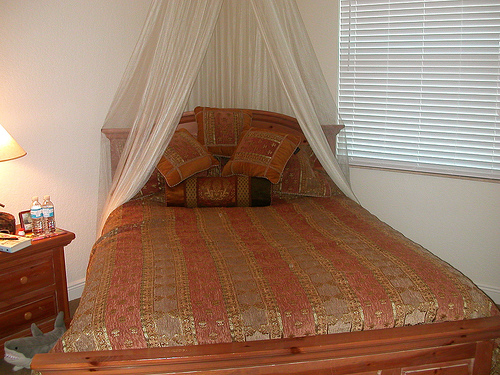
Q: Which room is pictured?
A: It is a bedroom.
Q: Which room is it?
A: It is a bedroom.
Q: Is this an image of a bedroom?
A: Yes, it is showing a bedroom.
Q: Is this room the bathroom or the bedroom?
A: It is the bedroom.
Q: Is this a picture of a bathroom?
A: No, the picture is showing a bedroom.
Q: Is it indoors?
A: Yes, it is indoors.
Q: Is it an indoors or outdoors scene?
A: It is indoors.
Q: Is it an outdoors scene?
A: No, it is indoors.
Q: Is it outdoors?
A: No, it is indoors.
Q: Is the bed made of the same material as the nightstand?
A: Yes, both the bed and the nightstand are made of wood.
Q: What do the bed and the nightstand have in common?
A: The material, both the bed and the nightstand are wooden.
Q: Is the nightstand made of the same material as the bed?
A: Yes, both the nightstand and the bed are made of wood.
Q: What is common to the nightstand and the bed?
A: The material, both the nightstand and the bed are wooden.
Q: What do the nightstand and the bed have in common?
A: The material, both the nightstand and the bed are wooden.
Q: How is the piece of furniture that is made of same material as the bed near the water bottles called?
A: The piece of furniture is a nightstand.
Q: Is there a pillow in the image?
A: Yes, there are pillows.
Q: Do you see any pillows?
A: Yes, there are pillows.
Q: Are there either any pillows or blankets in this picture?
A: Yes, there are pillows.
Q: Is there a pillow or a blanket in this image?
A: Yes, there are pillows.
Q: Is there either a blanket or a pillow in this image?
A: Yes, there are pillows.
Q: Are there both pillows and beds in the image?
A: Yes, there are both pillows and a bed.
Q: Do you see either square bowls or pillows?
A: Yes, there are square pillows.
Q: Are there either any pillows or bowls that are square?
A: Yes, the pillows are square.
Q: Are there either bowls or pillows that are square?
A: Yes, the pillows are square.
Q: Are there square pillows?
A: Yes, there are square pillows.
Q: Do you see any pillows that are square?
A: Yes, there are square pillows.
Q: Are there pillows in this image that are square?
A: Yes, there are square pillows.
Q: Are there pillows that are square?
A: Yes, there are pillows that are square.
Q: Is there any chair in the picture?
A: No, there are no chairs.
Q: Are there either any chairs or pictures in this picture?
A: No, there are no chairs or pictures.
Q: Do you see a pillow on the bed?
A: Yes, there are pillows on the bed.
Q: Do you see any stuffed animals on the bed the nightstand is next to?
A: No, there are pillows on the bed.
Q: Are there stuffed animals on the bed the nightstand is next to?
A: No, there are pillows on the bed.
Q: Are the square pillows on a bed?
A: Yes, the pillows are on a bed.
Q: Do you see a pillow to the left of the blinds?
A: Yes, there are pillows to the left of the blinds.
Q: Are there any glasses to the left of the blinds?
A: No, there are pillows to the left of the blinds.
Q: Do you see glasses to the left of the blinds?
A: No, there are pillows to the left of the blinds.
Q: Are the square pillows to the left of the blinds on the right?
A: Yes, the pillows are to the left of the blinds.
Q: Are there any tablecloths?
A: No, there are no tablecloths.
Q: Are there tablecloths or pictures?
A: No, there are no tablecloths or pictures.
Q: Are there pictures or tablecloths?
A: No, there are no tablecloths or pictures.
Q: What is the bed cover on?
A: The bed cover is on the bed.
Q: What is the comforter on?
A: The bed cover is on the bed.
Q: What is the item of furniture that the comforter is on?
A: The piece of furniture is a bed.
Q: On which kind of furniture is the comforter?
A: The comforter is on the bed.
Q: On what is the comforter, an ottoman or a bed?
A: The comforter is on a bed.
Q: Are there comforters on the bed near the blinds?
A: Yes, there is a comforter on the bed.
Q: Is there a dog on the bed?
A: No, there is a comforter on the bed.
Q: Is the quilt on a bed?
A: Yes, the quilt is on a bed.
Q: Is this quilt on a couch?
A: No, the quilt is on a bed.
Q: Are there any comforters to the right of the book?
A: Yes, there is a comforter to the right of the book.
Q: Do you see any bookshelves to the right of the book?
A: No, there is a comforter to the right of the book.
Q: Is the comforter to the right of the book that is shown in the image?
A: Yes, the comforter is to the right of the book.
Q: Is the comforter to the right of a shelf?
A: No, the comforter is to the right of the book.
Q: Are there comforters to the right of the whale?
A: Yes, there is a comforter to the right of the whale.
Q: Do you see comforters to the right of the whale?
A: Yes, there is a comforter to the right of the whale.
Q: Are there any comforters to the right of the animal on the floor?
A: Yes, there is a comforter to the right of the whale.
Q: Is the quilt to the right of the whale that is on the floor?
A: Yes, the quilt is to the right of the whale.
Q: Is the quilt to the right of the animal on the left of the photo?
A: Yes, the quilt is to the right of the whale.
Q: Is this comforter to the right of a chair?
A: No, the comforter is to the right of the whale.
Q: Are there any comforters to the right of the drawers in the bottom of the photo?
A: Yes, there is a comforter to the right of the drawers.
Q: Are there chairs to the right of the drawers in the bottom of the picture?
A: No, there is a comforter to the right of the drawers.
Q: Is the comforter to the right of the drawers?
A: Yes, the comforter is to the right of the drawers.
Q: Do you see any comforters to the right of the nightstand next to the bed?
A: Yes, there is a comforter to the right of the nightstand.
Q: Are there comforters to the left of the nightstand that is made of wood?
A: No, the comforter is to the right of the nightstand.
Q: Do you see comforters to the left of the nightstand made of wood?
A: No, the comforter is to the right of the nightstand.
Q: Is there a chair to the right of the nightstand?
A: No, there is a comforter to the right of the nightstand.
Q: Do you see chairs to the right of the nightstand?
A: No, there is a comforter to the right of the nightstand.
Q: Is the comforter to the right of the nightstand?
A: Yes, the comforter is to the right of the nightstand.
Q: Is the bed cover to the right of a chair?
A: No, the bed cover is to the right of the nightstand.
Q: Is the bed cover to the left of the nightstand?
A: No, the bed cover is to the right of the nightstand.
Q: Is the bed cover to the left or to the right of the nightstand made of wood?
A: The bed cover is to the right of the nightstand.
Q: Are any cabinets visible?
A: No, there are no cabinets.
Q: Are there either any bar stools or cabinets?
A: No, there are no cabinets or bar stools.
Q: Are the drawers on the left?
A: Yes, the drawers are on the left of the image.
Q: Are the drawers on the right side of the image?
A: No, the drawers are on the left of the image.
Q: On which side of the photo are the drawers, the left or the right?
A: The drawers are on the left of the image.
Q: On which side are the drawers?
A: The drawers are on the left of the image.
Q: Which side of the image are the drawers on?
A: The drawers are on the left of the image.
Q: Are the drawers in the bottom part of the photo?
A: Yes, the drawers are in the bottom of the image.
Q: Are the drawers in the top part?
A: No, the drawers are in the bottom of the image.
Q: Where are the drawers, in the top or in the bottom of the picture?
A: The drawers are in the bottom of the image.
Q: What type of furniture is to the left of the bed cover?
A: The pieces of furniture are drawers.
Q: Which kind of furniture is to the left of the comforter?
A: The pieces of furniture are drawers.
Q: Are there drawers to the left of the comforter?
A: Yes, there are drawers to the left of the comforter.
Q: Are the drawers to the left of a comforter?
A: Yes, the drawers are to the left of a comforter.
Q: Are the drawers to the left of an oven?
A: No, the drawers are to the left of a comforter.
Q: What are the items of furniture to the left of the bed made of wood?
A: The pieces of furniture are drawers.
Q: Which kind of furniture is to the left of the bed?
A: The pieces of furniture are drawers.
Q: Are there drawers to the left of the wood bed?
A: Yes, there are drawers to the left of the bed.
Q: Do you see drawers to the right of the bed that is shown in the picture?
A: No, the drawers are to the left of the bed.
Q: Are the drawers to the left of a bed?
A: Yes, the drawers are to the left of a bed.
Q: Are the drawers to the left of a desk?
A: No, the drawers are to the left of a bed.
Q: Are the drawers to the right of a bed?
A: No, the drawers are to the left of a bed.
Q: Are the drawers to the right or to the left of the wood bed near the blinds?
A: The drawers are to the left of the bed.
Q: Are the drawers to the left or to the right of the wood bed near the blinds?
A: The drawers are to the left of the bed.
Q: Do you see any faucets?
A: No, there are no faucets.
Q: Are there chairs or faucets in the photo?
A: No, there are no faucets or chairs.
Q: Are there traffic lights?
A: No, there are no traffic lights.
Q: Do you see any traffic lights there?
A: No, there are no traffic lights.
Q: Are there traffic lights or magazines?
A: No, there are no traffic lights or magazines.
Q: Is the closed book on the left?
A: Yes, the book is on the left of the image.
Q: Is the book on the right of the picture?
A: No, the book is on the left of the image.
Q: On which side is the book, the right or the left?
A: The book is on the left of the image.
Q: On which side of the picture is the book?
A: The book is on the left of the image.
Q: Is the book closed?
A: Yes, the book is closed.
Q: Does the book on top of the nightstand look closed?
A: Yes, the book is closed.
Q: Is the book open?
A: No, the book is closed.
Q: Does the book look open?
A: No, the book is closed.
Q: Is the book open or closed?
A: The book is closed.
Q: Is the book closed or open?
A: The book is closed.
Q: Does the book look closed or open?
A: The book is closed.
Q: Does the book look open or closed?
A: The book is closed.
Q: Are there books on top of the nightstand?
A: Yes, there is a book on top of the nightstand.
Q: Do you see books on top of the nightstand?
A: Yes, there is a book on top of the nightstand.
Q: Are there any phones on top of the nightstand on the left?
A: No, there is a book on top of the nightstand.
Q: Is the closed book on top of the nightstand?
A: Yes, the book is on top of the nightstand.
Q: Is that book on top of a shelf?
A: No, the book is on top of the nightstand.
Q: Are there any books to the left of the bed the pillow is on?
A: Yes, there is a book to the left of the bed.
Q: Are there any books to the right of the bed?
A: No, the book is to the left of the bed.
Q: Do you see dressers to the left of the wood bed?
A: No, there is a book to the left of the bed.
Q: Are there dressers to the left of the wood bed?
A: No, there is a book to the left of the bed.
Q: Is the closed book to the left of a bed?
A: Yes, the book is to the left of a bed.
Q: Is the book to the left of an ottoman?
A: No, the book is to the left of a bed.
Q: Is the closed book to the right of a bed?
A: No, the book is to the left of a bed.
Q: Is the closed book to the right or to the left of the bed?
A: The book is to the left of the bed.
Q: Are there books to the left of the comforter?
A: Yes, there is a book to the left of the comforter.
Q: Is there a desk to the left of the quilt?
A: No, there is a book to the left of the quilt.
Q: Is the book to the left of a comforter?
A: Yes, the book is to the left of a comforter.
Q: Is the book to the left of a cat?
A: No, the book is to the left of a comforter.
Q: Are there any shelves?
A: No, there are no shelves.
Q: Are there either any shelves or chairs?
A: No, there are no shelves or chairs.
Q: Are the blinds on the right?
A: Yes, the blinds are on the right of the image.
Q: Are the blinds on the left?
A: No, the blinds are on the right of the image.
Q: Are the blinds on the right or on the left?
A: The blinds are on the right of the image.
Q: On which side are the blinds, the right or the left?
A: The blinds are on the right of the image.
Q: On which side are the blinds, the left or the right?
A: The blinds are on the right of the image.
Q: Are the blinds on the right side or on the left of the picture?
A: The blinds are on the right of the image.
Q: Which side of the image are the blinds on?
A: The blinds are on the right of the image.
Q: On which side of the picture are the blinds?
A: The blinds are on the right of the image.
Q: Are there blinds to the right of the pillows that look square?
A: Yes, there are blinds to the right of the pillows.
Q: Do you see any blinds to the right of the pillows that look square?
A: Yes, there are blinds to the right of the pillows.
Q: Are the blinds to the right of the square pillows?
A: Yes, the blinds are to the right of the pillows.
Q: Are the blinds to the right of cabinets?
A: No, the blinds are to the right of the pillows.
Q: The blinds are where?
A: The blinds are in the bedroom.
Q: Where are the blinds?
A: The blinds are in the bedroom.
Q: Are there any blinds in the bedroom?
A: Yes, there are blinds in the bedroom.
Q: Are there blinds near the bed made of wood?
A: Yes, there are blinds near the bed.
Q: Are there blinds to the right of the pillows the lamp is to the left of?
A: Yes, there are blinds to the right of the pillows.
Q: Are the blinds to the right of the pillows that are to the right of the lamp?
A: Yes, the blinds are to the right of the pillows.